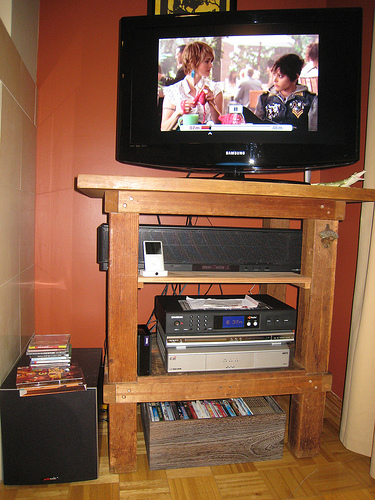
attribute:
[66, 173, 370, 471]
stand — brown, wooden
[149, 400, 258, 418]
books — some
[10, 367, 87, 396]
pile — books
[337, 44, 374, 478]
curtain — brown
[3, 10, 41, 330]
wall — tiled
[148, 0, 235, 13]
picture — yellow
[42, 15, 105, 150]
wall — orange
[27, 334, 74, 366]
stack — cd boxes